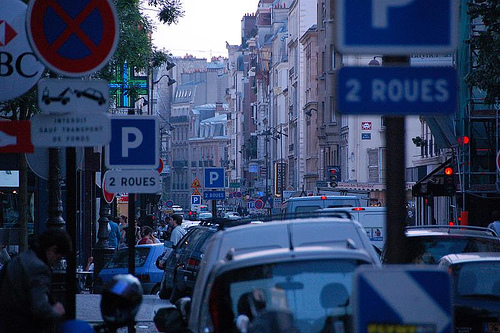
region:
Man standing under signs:
[0, 214, 87, 328]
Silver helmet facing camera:
[84, 257, 158, 331]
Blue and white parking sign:
[190, 155, 237, 219]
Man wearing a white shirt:
[158, 207, 188, 247]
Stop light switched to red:
[437, 160, 462, 202]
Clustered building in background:
[147, 55, 399, 190]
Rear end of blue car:
[91, 238, 175, 298]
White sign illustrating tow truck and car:
[25, 79, 125, 125]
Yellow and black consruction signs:
[180, 162, 207, 217]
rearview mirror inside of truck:
[256, 267, 316, 304]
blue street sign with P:
[106, 118, 160, 160]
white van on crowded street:
[211, 214, 387, 327]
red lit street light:
[437, 164, 457, 185]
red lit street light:
[456, 133, 473, 146]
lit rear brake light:
[309, 192, 324, 202]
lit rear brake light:
[356, 200, 366, 215]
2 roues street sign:
[108, 172, 175, 200]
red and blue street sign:
[33, 1, 118, 69]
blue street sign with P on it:
[202, 169, 228, 184]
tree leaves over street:
[130, 2, 178, 81]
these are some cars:
[195, 197, 372, 299]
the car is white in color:
[241, 226, 317, 241]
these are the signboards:
[40, 73, 163, 195]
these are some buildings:
[171, 0, 329, 201]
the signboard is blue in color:
[402, 17, 439, 39]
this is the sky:
[193, 4, 227, 35]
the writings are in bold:
[123, 175, 155, 187]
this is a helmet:
[100, 270, 146, 325]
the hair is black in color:
[41, 229, 62, 242]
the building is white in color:
[278, 73, 284, 90]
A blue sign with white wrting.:
[341, 68, 462, 113]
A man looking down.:
[1, 225, 78, 327]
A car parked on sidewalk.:
[151, 226, 206, 303]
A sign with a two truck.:
[31, 76, 113, 146]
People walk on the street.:
[108, 213, 182, 243]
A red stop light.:
[324, 160, 344, 190]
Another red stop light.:
[438, 161, 458, 198]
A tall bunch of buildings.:
[154, 11, 328, 198]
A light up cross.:
[109, 58, 151, 114]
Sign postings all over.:
[187, 167, 226, 222]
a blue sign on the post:
[331, 62, 461, 117]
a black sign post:
[377, 115, 409, 265]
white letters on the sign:
[343, 71, 450, 107]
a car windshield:
[201, 252, 375, 332]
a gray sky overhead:
[134, 0, 260, 65]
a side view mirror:
[146, 303, 183, 331]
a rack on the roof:
[221, 235, 361, 264]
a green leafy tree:
[107, 0, 193, 75]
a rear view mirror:
[271, 272, 315, 296]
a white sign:
[99, 167, 163, 193]